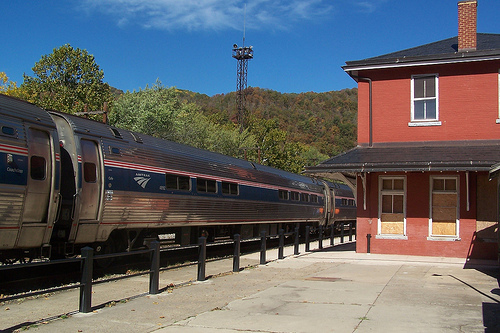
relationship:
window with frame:
[409, 71, 443, 128] [401, 69, 451, 136]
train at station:
[2, 90, 357, 278] [2, 234, 498, 331]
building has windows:
[307, 1, 500, 257] [371, 171, 464, 243]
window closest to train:
[371, 173, 411, 244] [2, 90, 357, 278]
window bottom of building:
[423, 171, 463, 243] [307, 1, 500, 257]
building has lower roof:
[307, 1, 500, 257] [295, 137, 500, 178]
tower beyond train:
[227, 29, 257, 86] [2, 90, 357, 278]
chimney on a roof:
[454, 0, 482, 55] [333, 27, 500, 74]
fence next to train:
[22, 218, 354, 290] [2, 90, 357, 278]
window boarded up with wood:
[371, 173, 411, 244] [381, 181, 400, 232]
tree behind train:
[14, 41, 116, 113] [2, 90, 357, 278]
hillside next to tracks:
[197, 78, 353, 148] [22, 218, 354, 290]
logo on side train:
[131, 167, 156, 192] [2, 90, 357, 278]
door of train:
[75, 134, 108, 226] [2, 90, 357, 278]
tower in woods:
[227, 29, 257, 86] [5, 74, 356, 150]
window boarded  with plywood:
[371, 173, 411, 244] [381, 181, 400, 232]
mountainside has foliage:
[197, 78, 353, 148] [5, 74, 356, 150]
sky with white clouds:
[6, 2, 445, 42] [96, 2, 349, 39]